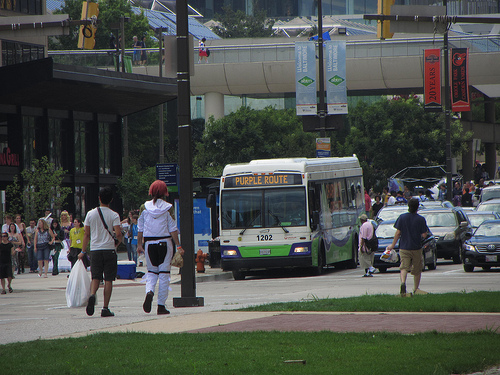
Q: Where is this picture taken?
A: A street.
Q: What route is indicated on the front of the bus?
A: Purple route.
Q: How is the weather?
A: Overcast.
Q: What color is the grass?
A: Green.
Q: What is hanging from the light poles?
A: Flags.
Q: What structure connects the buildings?
A: A bridge.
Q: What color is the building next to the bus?
A: Black.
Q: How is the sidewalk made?
A: Of concrete.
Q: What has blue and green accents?
A: A white bus.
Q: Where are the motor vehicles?
A: Driving down the street.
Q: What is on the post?
A: Street signs.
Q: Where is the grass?
A: On the ground.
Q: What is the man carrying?
A: Plastic bag.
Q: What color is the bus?
A: White and green.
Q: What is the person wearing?
A: White clothes.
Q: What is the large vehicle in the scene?
A: Bus.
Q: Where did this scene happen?
A: Busy street.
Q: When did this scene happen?
A: Daytime.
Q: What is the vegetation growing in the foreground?
A: Grass.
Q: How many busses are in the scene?
A: One.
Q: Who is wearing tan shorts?
A: A man.